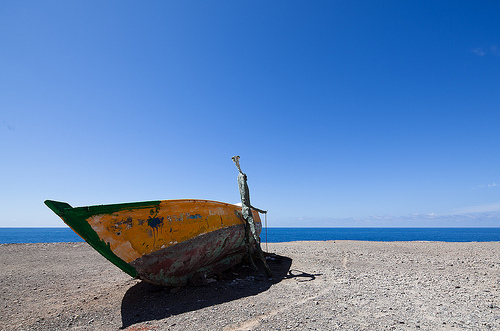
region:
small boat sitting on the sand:
[40, 192, 315, 299]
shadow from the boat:
[113, 246, 301, 326]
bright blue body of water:
[1, 226, 498, 243]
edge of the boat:
[41, 200, 63, 210]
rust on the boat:
[145, 213, 166, 242]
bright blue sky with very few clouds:
[3, 0, 499, 228]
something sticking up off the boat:
[228, 147, 259, 219]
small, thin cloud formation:
[303, 203, 496, 221]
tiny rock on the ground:
[311, 298, 322, 306]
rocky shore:
[1, 243, 499, 328]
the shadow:
[114, 295, 139, 320]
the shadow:
[152, 297, 168, 329]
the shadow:
[138, 303, 157, 330]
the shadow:
[147, 306, 161, 319]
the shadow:
[132, 306, 149, 320]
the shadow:
[142, 297, 160, 319]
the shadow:
[137, 288, 147, 319]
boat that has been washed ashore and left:
[38, 135, 306, 297]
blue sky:
[133, 60, 433, 141]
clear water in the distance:
[292, 220, 493, 241]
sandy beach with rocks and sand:
[295, 250, 471, 296]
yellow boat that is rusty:
[77, 173, 265, 284]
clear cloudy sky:
[393, 188, 498, 218]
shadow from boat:
[123, 261, 291, 311]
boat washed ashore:
[48, 117, 393, 302]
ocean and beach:
[292, 173, 478, 308]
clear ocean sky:
[207, 93, 490, 177]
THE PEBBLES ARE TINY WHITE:
[329, 290, 361, 319]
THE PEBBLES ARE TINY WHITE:
[314, 286, 329, 316]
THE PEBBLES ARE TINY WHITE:
[293, 287, 333, 328]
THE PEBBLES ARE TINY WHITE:
[312, 294, 332, 322]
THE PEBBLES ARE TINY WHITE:
[305, 301, 327, 319]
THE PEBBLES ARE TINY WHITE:
[307, 290, 327, 325]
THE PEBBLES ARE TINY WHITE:
[302, 289, 338, 317]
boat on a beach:
[68, 151, 309, 309]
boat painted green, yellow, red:
[57, 164, 297, 286]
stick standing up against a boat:
[198, 142, 295, 297]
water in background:
[8, 204, 495, 294]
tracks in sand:
[235, 232, 370, 329]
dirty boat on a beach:
[51, 140, 272, 302]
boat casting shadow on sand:
[44, 184, 286, 326]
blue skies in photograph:
[5, 47, 450, 204]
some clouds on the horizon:
[370, 192, 495, 230]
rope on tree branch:
[237, 182, 344, 284]